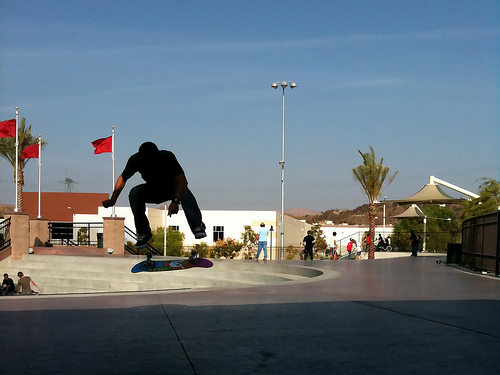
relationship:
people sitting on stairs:
[5, 269, 37, 299] [3, 255, 323, 299]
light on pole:
[290, 78, 296, 88] [280, 91, 285, 256]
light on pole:
[279, 78, 287, 88] [280, 91, 285, 256]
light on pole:
[268, 79, 278, 89] [280, 91, 285, 256]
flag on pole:
[92, 135, 113, 153] [110, 124, 117, 209]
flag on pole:
[19, 141, 40, 159] [34, 131, 44, 218]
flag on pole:
[0, 118, 17, 136] [10, 105, 19, 215]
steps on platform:
[4, 252, 321, 290] [243, 269, 460, 353]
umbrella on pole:
[391, 182, 457, 207] [425, 171, 487, 203]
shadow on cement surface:
[147, 291, 434, 354] [34, 285, 475, 361]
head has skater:
[135, 141, 162, 162] [98, 140, 208, 251]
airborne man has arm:
[101, 140, 207, 248] [165, 161, 190, 206]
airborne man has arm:
[101, 140, 207, 248] [112, 156, 139, 194]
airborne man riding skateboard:
[101, 140, 207, 248] [131, 246, 218, 278]